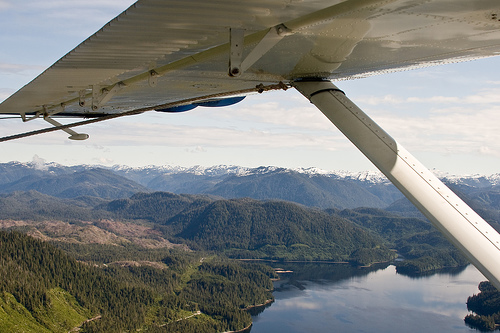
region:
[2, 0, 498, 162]
white wing of plane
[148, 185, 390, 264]
grass covered mountain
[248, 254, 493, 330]
body of water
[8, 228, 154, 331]
green trees lining hill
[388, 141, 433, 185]
nails in white plane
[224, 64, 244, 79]
bolt on wing of plane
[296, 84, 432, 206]
shadow on plane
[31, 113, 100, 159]
white handle protruding from white wing of plane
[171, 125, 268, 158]
white and grey clouds in blue sky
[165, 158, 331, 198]
snow covered mountain tops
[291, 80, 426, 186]
shadow on airplane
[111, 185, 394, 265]
grass covered mountain before water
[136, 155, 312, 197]
snow covered mountain in horizon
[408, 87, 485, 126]
white cloud in blue sky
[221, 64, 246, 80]
bolt in white plane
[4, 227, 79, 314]
green trees and foliage on hill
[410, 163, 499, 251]
line of bolts in white plane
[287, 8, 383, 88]
reflection of white pole on underside of plane wing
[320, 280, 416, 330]
water reflecting the landscape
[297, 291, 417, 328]
water reflecting the skies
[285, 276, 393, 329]
water reflecting the greenery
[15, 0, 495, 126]
wing of an airplane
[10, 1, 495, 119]
white wing of an airplane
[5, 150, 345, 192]
white snow peaked mountains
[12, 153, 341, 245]
white snow peaked mountains with trees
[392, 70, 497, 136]
blue sky with white clouds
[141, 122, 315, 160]
blue sky with white clouds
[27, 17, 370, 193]
the wing of the plane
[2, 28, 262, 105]
the wing of the plane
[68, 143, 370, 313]
the hills are visible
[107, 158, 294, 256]
the hills are visible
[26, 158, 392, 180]
snow on the mountains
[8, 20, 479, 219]
the wing of an airplane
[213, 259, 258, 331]
trees next to the water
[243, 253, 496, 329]
a body of water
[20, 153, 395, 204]
a mountain in the distance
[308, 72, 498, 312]
a pole on the wing of the plane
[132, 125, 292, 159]
clouds in the sky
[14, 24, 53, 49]
the blue part of the sky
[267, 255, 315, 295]
a reflection in the water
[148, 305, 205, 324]
a road in the trees